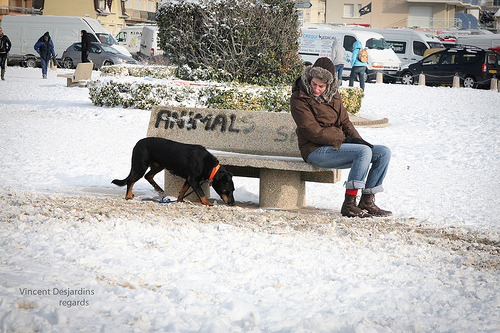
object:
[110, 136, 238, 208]
dog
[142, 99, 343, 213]
bench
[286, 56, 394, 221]
woman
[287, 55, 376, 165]
jacket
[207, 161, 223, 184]
collar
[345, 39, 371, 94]
woman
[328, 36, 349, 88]
woman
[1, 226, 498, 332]
ground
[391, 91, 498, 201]
snow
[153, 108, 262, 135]
graffiti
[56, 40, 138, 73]
vehicles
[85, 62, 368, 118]
bushes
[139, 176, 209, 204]
leash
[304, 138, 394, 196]
jeans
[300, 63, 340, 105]
fur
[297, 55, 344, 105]
hood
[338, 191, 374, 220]
boots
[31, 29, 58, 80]
man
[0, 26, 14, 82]
man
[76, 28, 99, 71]
man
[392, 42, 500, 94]
car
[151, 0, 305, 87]
bush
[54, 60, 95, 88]
bench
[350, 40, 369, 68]
coat